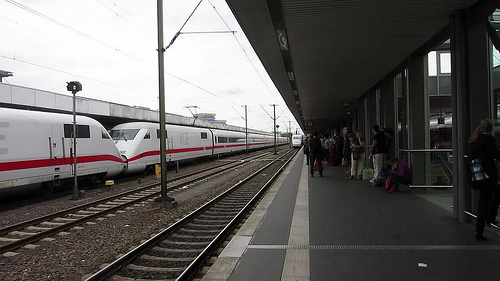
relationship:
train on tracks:
[290, 133, 303, 147] [82, 147, 298, 278]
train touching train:
[1, 106, 124, 204] [107, 122, 290, 177]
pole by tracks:
[158, 0, 164, 200] [82, 147, 298, 278]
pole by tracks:
[158, 0, 164, 200] [0, 144, 287, 256]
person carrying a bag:
[309, 131, 324, 175] [311, 159, 321, 171]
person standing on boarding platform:
[309, 131, 324, 175] [202, 144, 497, 278]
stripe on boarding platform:
[281, 152, 311, 281] [202, 144, 497, 278]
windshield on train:
[109, 129, 139, 141] [107, 122, 290, 177]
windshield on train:
[293, 137, 301, 140] [290, 133, 303, 147]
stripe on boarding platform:
[201, 144, 304, 278] [202, 144, 497, 278]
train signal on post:
[65, 81, 83, 96] [71, 93, 80, 201]